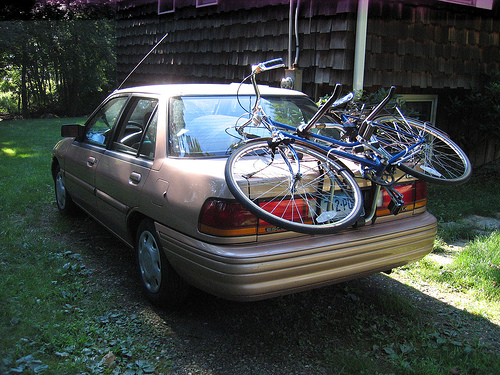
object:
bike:
[225, 56, 474, 233]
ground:
[2, 287, 499, 372]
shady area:
[4, 131, 496, 371]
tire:
[132, 221, 182, 312]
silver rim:
[137, 229, 162, 295]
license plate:
[316, 191, 369, 224]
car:
[53, 81, 439, 303]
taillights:
[196, 198, 259, 238]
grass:
[0, 120, 500, 372]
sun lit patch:
[425, 235, 500, 327]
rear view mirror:
[148, 100, 161, 107]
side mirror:
[61, 124, 83, 138]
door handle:
[87, 156, 98, 164]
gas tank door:
[151, 178, 170, 206]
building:
[116, 2, 496, 200]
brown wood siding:
[328, 33, 355, 50]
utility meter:
[280, 76, 294, 91]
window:
[115, 94, 158, 155]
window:
[157, 0, 177, 15]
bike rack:
[292, 83, 403, 229]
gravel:
[132, 301, 413, 350]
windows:
[194, 0, 219, 7]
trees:
[60, 0, 106, 116]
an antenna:
[82, 31, 168, 109]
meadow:
[15, 66, 48, 112]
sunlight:
[121, 83, 305, 154]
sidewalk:
[439, 210, 497, 265]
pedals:
[357, 122, 405, 217]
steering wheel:
[118, 122, 146, 148]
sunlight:
[2, 66, 64, 121]